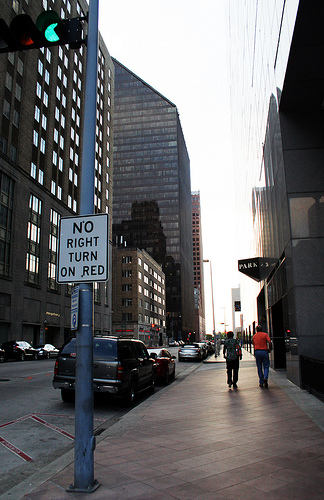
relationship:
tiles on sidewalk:
[101, 437, 323, 499] [1, 364, 322, 499]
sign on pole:
[57, 214, 108, 284] [67, 0, 99, 492]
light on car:
[116, 365, 124, 381] [52, 336, 156, 406]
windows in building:
[27, 45, 85, 214] [0, 0, 115, 351]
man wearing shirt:
[253, 325, 272, 388] [252, 331, 270, 352]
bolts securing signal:
[67, 15, 81, 44] [0, 13, 81, 48]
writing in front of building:
[43, 310, 63, 320] [0, 0, 115, 351]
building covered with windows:
[0, 0, 115, 351] [27, 45, 85, 214]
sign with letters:
[57, 214, 108, 284] [62, 221, 104, 277]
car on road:
[52, 334, 157, 406] [1, 337, 219, 499]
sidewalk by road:
[1, 364, 322, 499] [1, 337, 219, 499]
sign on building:
[237, 257, 277, 285] [229, 0, 324, 402]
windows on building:
[27, 45, 85, 214] [0, 0, 115, 351]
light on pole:
[44, 21, 63, 43] [67, 0, 99, 492]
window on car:
[117, 342, 147, 359] [52, 334, 157, 406]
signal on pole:
[0, 13, 81, 48] [67, 0, 99, 492]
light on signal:
[44, 21, 63, 43] [0, 13, 88, 54]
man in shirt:
[253, 325, 272, 388] [252, 331, 270, 352]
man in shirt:
[223, 331, 244, 391] [223, 337, 242, 362]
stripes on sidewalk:
[0, 414, 76, 463] [1, 363, 324, 499]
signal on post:
[0, 13, 81, 48] [67, 0, 99, 492]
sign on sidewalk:
[57, 214, 108, 284] [1, 363, 324, 499]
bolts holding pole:
[66, 478, 101, 493] [67, 0, 99, 492]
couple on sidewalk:
[223, 324, 272, 390] [1, 364, 322, 499]